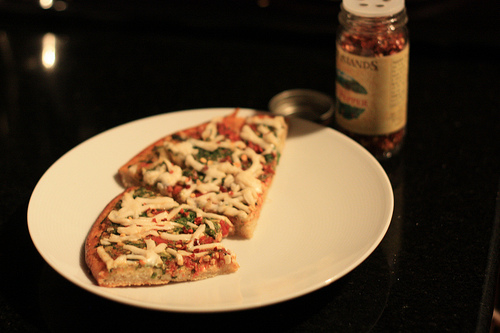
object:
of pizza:
[81, 185, 244, 289]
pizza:
[68, 101, 309, 291]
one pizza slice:
[112, 110, 292, 241]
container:
[331, 0, 409, 157]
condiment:
[347, 33, 394, 50]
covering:
[342, 1, 405, 19]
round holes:
[373, 3, 388, 10]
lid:
[269, 81, 336, 119]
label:
[326, 47, 422, 132]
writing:
[336, 53, 378, 125]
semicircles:
[330, 68, 373, 121]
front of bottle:
[332, 71, 369, 125]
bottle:
[330, 1, 414, 161]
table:
[6, 5, 264, 99]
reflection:
[39, 28, 61, 74]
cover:
[342, 1, 414, 19]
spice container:
[334, 16, 418, 160]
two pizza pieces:
[80, 106, 293, 288]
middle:
[83, 106, 311, 308]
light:
[41, 31, 58, 74]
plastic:
[335, 17, 413, 51]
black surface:
[64, 10, 304, 82]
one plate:
[22, 101, 396, 315]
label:
[384, 51, 409, 129]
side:
[384, 52, 412, 129]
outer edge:
[84, 234, 93, 279]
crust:
[82, 204, 99, 281]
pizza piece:
[81, 185, 233, 284]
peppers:
[347, 38, 400, 51]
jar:
[335, 11, 412, 53]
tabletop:
[61, 14, 271, 97]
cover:
[266, 89, 336, 117]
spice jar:
[332, 0, 415, 152]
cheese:
[116, 199, 146, 224]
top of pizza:
[83, 183, 242, 287]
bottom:
[78, 235, 93, 282]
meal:
[21, 0, 458, 314]